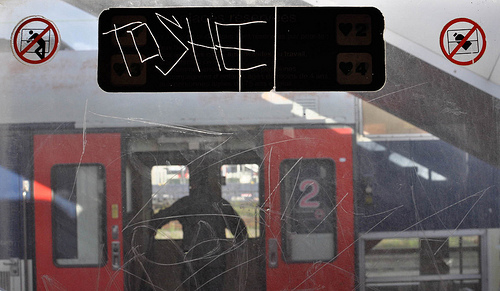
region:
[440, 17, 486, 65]
no bottles warning label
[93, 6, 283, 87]
graffiti on plastic window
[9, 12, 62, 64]
no passenger leaning warning label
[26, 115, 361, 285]
doors opening to station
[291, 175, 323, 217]
number labeled near the door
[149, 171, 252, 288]
person exiting the station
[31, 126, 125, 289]
bright door is open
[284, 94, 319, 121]
ac vent for tram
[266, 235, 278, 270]
single door handle installed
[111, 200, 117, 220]
warning labels on door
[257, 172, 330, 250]
part of a glass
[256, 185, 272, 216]
part of a line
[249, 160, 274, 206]
edge of a door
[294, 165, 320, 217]
part of a number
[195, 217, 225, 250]
part of a jacket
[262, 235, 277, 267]
part of a handle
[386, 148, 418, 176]
part of a stair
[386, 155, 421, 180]
edge of a stair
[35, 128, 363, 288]
The doors are open.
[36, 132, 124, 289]
A single red door.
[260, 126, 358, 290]
Another red door labelled.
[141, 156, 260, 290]
A man staning in a doorway.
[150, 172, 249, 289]
The silhouette of a man.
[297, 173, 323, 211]
A red labelled two.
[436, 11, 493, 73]
A no drinking sticker.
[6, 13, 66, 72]
A no leaning over sticker.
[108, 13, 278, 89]
Graffiti on the wall.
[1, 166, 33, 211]
A light cast on the wall.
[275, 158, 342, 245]
the number 2 in red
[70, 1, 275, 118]
white writing on sign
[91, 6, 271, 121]
white writing on black background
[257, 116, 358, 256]
red door of vehicle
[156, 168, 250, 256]
shape of a person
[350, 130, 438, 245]
window of the train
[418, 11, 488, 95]
red and white sign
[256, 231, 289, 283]
silver handle of door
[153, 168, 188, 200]
building in the background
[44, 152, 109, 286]
window on the door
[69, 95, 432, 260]
window is covered in scratches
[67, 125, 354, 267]
doors of train are open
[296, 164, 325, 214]
train car with number 2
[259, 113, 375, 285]
a red door in open opsition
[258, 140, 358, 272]
door has a small rectangular window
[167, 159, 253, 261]
sillouette of a person standing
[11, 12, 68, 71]
information decal in corner of window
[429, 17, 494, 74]
no beverages sign on window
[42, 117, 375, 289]
both doors are in open position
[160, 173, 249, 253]
person standing in front of a window